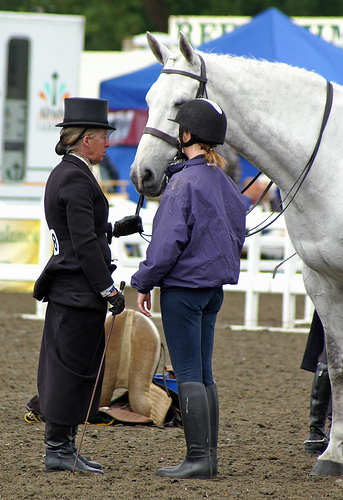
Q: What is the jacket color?
A: Purple.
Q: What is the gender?
A: Female.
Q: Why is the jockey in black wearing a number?
A: The jockey is competing.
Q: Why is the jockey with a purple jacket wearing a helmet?
A: To protect her head.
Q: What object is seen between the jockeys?
A: A saddle.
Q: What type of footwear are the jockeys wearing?
A: Boots.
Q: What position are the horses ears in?
A: They are facing forward.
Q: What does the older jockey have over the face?
A: A net.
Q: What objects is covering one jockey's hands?
A: Gloves.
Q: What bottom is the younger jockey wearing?
A: Blue Jeans.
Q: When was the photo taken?
A: During the daytime.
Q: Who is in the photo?
A: Two people.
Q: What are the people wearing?
A: Hats.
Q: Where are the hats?
A: On the people.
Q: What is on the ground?
A: Dirt.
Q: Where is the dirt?
A: On the ground.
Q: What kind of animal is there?
A: Horse.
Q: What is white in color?
A: Horse.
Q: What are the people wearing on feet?
A: Boots.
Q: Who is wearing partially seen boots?
A: The woman in all black.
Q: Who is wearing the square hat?
A: The woman in all black.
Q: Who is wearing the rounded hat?
A: The woman wearing a purple jacket.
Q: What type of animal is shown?
A: Horse.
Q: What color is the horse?
A: White.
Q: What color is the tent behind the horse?
A: Blue.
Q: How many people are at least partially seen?
A: Three.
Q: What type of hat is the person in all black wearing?
A: Top hat.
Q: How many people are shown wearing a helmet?
A: One.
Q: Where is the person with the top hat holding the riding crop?
A: Right hand.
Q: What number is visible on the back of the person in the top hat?
A: Eight.